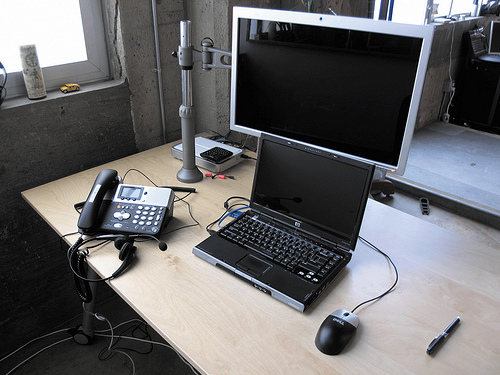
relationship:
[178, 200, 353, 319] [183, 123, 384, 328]
keyboard of laptop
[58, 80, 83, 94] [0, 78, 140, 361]
car on window sill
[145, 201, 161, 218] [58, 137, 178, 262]
button on phone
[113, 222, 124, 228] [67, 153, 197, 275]
button on phone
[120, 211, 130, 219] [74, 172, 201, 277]
button on phone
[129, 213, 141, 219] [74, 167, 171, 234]
button on phone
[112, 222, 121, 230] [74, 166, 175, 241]
button on phone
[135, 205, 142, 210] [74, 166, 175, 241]
button on phone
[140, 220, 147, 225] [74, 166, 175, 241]
button on phone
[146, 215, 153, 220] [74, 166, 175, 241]
button on phone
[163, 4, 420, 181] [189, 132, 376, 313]
monitor of laptop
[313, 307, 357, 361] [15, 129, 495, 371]
mouse on desk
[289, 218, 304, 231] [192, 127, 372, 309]
logo on laptop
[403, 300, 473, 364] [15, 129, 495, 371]
pen on desk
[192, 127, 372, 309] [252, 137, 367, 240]
laptop has screen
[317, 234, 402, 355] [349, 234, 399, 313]
mouse has cord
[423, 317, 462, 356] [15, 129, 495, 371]
pen on desk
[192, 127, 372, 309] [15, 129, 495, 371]
laptop sitting on desk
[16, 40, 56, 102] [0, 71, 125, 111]
candle on window sill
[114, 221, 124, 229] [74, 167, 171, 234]
button on phone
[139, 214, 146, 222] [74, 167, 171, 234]
button on phone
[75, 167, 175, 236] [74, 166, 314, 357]
phone on desk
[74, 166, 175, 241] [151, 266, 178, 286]
phone sitting on top of desk